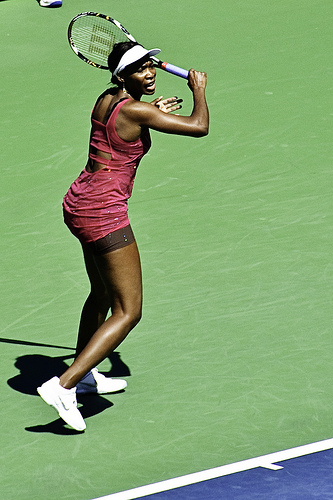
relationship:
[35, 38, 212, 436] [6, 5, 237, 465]
she playing tennis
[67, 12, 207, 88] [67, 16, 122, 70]
tennis racket with net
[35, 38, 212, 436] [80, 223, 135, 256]
she wearing bottom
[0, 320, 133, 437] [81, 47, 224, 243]
shadow of woman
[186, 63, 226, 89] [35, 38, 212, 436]
hand of she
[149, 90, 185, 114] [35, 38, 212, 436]
hand of she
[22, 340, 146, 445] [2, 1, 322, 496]
shoes on turf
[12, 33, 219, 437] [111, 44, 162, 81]
she wearing cap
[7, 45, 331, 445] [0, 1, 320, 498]
turf on court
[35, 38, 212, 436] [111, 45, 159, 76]
she wearing visor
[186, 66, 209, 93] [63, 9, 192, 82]
hand holding tennis racket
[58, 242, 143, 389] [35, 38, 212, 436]
leg of she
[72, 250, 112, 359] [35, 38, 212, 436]
leg of she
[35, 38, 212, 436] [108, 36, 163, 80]
she wearing visor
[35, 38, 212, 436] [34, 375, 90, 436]
she wearing shoes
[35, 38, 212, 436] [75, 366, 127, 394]
she wearing white shoe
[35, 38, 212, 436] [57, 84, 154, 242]
she wearing top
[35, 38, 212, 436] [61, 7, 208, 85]
she playing tennis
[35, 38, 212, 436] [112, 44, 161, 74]
she wearing cap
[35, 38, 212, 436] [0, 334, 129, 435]
she casting shadow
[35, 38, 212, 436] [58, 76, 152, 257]
she wearing outfit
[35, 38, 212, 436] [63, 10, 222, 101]
she holding racket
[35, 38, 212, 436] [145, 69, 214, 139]
she has bent arm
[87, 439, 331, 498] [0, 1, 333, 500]
white line on court